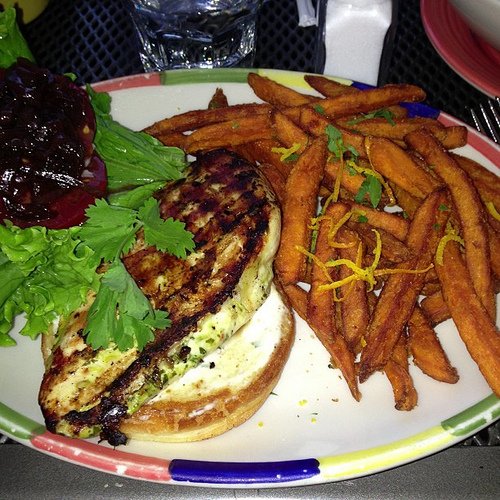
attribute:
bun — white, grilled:
[32, 252, 296, 445]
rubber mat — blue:
[11, 2, 498, 136]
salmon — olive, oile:
[101, 176, 379, 388]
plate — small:
[419, 0, 499, 103]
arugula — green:
[0, 79, 195, 350]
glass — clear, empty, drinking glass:
[123, 0, 266, 74]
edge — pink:
[418, 1, 498, 103]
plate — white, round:
[5, 66, 496, 495]